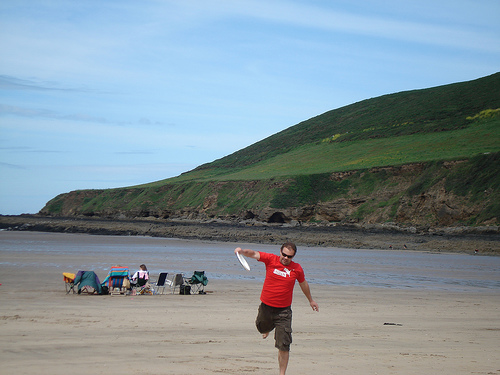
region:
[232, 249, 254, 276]
white frisbee in hand of man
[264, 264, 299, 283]
white design on front of shirt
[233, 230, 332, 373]
man in red shirt on beach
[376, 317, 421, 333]
small black rock laying on beach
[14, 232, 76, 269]
small ripples on surface of water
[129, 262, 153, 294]
woman sitting in chair on beach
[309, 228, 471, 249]
water shore covered in gravel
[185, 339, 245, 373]
footprints in beach sand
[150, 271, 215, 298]
row of chairs on beach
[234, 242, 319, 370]
The playful young man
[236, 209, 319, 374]
The man holding a frisbee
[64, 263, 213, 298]
The picnic setup on a shoreline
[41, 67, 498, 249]
The raised green hill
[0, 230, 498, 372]
A gray open shore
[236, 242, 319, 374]
The man wearing shorts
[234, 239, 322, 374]
The man in a red t-shirt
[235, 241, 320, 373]
The man wearing dark glasses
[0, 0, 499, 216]
An extensive blue sky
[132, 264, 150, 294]
The seated person in the background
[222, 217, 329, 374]
he is on the beach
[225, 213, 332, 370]
he is playing on the beach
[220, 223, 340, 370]
a man running on the sand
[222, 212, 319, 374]
a man playing frisbee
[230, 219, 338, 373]
he is playing frisbee on the beach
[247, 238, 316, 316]
this is a red tee shirt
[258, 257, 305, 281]
the logo is white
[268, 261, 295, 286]
this is the Puma logo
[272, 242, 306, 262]
a pair of black sunglasses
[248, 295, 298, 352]
dark brown cargo shorts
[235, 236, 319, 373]
man's shirt is red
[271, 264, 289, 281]
white letters on man's shirt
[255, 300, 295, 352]
man's shorts are brown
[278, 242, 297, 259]
man is wearing sunglasses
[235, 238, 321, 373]
man holding a frisbee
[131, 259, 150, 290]
person sitting in a chair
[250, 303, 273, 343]
man's leg off the ground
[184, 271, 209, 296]
chair is green and black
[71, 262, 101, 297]
jacket is green and purple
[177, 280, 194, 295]
black bag on ground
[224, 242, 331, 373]
a man catching a frisbee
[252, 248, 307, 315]
a red tee shirt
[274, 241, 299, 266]
the head of a man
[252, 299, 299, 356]
a pair of olive cargo short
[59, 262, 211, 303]
a group of fold up chairs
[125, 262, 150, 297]
a woman sitting on the beach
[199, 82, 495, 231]
a green grassy hill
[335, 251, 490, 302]
shallow water on the shore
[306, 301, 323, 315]
the hand of a man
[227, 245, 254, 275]
a frisbee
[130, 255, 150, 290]
person sitting in a lawn chair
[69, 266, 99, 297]
jacket draped over a lawnchair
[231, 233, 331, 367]
man holding a white frisbee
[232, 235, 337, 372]
man wearing red and white shirt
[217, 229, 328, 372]
man is running through the sand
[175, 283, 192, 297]
black bag on the ground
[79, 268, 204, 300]
chairs are on the beach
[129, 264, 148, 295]
woman in the chair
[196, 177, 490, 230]
grass is on the cliff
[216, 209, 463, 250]
rocks on the beach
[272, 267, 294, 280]
logo on the shirt